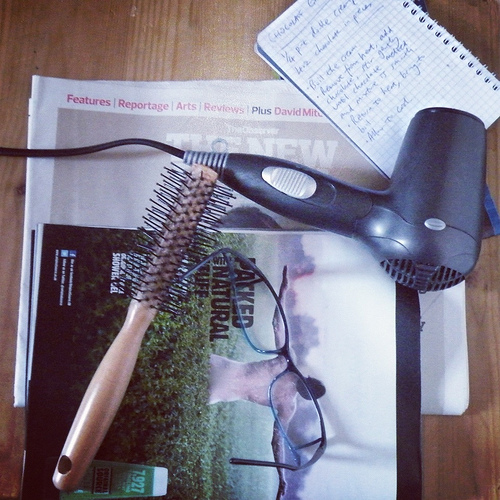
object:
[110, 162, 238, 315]
brissles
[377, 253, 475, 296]
vent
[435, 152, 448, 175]
ground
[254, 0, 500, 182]
notepad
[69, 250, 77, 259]
logo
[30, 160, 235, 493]
brown hairbrush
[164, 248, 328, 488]
eyeglasses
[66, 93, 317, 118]
writings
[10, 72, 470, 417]
magazine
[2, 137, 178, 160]
cord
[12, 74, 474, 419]
notebook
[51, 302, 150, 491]
brush handle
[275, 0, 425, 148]
notes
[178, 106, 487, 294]
blowdryer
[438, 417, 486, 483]
woodgrain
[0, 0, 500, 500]
desk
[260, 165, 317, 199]
switch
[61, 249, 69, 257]
logo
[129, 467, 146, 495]
numbers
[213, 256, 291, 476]
blue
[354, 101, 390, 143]
handwritten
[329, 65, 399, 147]
written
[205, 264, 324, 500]
person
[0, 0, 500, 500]
table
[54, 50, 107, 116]
table top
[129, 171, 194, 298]
hair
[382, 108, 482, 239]
top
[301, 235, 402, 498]
part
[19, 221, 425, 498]
magazine